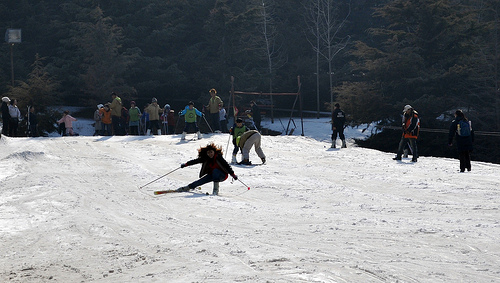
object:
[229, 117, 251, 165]
child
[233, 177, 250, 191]
pole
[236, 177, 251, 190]
skis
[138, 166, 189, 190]
skis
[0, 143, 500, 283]
tracks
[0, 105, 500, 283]
ground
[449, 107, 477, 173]
person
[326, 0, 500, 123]
leaves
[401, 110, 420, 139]
jacket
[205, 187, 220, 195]
ski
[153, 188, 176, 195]
ski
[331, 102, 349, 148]
man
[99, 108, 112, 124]
jacket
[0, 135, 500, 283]
ski slope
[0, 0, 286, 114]
trees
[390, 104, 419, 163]
man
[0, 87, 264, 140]
people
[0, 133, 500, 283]
downhill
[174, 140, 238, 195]
person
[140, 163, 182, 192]
ski pole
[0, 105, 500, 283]
snow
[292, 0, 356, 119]
tree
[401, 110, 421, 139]
coat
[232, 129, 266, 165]
guy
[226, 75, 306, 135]
tripod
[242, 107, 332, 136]
fence